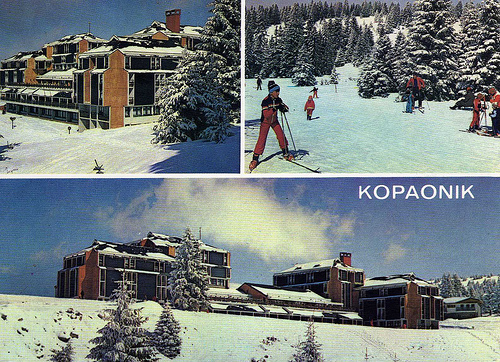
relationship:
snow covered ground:
[184, 316, 246, 360] [0, 291, 483, 360]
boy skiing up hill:
[248, 83, 296, 168] [244, 74, 484, 171]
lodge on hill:
[51, 229, 444, 329] [0, 291, 484, 360]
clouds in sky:
[94, 176, 357, 262] [1, 178, 484, 295]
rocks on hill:
[44, 302, 84, 342] [0, 291, 484, 360]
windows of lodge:
[124, 270, 142, 283] [51, 229, 444, 329]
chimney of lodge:
[338, 249, 353, 267] [51, 229, 444, 329]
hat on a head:
[266, 76, 278, 94] [266, 79, 282, 101]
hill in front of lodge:
[0, 291, 484, 360] [51, 229, 444, 329]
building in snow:
[52, 230, 443, 330] [47, 294, 480, 345]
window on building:
[335, 268, 350, 280] [52, 230, 443, 330]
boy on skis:
[248, 82, 317, 143] [255, 133, 377, 180]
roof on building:
[224, 272, 347, 304] [195, 267, 368, 333]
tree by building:
[72, 283, 155, 353] [119, 224, 403, 313]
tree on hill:
[350, 33, 493, 106] [256, 25, 452, 160]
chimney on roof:
[144, 5, 188, 38] [105, 13, 208, 57]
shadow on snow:
[129, 130, 232, 181] [83, 95, 205, 194]